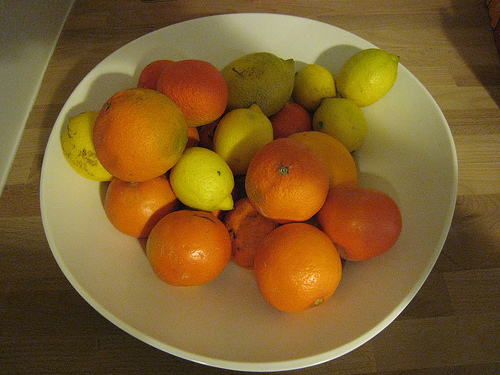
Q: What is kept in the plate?
A: Fruits.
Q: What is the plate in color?
A: White.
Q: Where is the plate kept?
A: On a table.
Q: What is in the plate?
A: Oranges and lemons.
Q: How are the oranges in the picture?
A: Ripe.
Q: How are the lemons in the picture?
A: Ripened.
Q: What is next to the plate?
A: Wall.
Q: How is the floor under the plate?
A: Clean.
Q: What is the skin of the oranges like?
A: Green and orange.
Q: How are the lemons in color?
A: Yellow.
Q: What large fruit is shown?
A: A orange.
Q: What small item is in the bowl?
A: A lemon.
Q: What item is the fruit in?
A: A bowl.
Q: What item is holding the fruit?
A: A plate.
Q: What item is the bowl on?
A: The table.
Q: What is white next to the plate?
A: A napkin.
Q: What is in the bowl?
A: Fruit.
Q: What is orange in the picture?
A: Oranges.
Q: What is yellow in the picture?
A: Lemons.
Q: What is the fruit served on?
A: A white platter.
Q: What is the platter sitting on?
A: A table.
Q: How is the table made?
A: Of wood.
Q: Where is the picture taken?
A: A kitchen.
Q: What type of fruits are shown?
A: Citrus.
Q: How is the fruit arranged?
A: In a pile.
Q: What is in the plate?
A: Food.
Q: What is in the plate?
A: Fruits.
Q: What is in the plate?
A: Oranges.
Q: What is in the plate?
A: Lemons.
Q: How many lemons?
A: 7.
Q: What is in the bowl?
A: Lemons and oranges.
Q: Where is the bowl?
A: On the counter.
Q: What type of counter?
A: Wood.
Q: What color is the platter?
A: White.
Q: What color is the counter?
A: Light brown.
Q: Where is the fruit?
A: Platter.